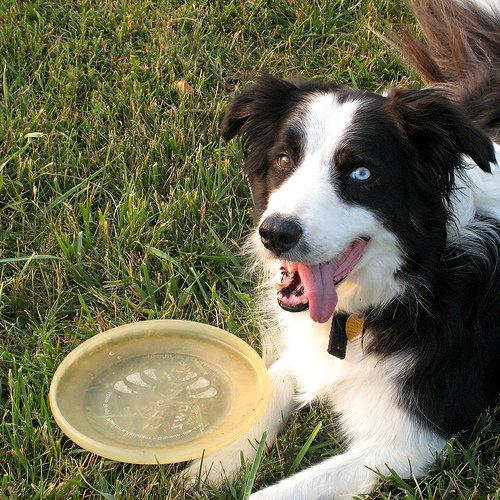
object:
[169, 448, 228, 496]
paw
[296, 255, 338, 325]
tongue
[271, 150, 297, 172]
eye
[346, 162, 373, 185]
eye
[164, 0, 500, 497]
dog